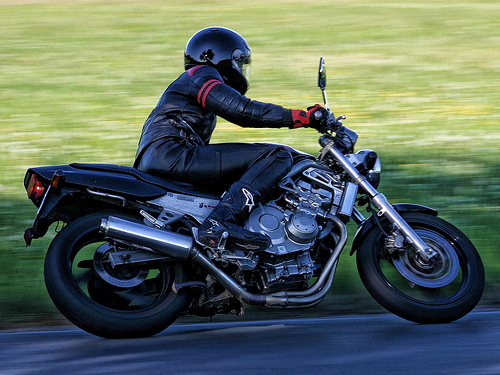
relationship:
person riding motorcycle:
[138, 26, 328, 248] [25, 57, 486, 339]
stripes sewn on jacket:
[193, 78, 222, 108] [133, 65, 293, 167]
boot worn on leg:
[194, 182, 272, 253] [177, 143, 292, 254]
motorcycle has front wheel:
[25, 57, 486, 339] [357, 213, 485, 323]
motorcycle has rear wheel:
[25, 57, 486, 339] [44, 211, 196, 339]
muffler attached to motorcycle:
[98, 215, 194, 257] [25, 57, 486, 339]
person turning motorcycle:
[138, 26, 328, 248] [25, 57, 486, 339]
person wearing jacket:
[138, 26, 328, 248] [133, 65, 293, 167]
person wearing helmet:
[138, 26, 328, 248] [184, 26, 252, 95]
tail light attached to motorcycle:
[26, 173, 46, 198] [25, 57, 486, 339]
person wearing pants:
[138, 26, 328, 248] [134, 137, 317, 194]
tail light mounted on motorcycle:
[26, 173, 46, 198] [25, 57, 486, 339]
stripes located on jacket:
[193, 78, 222, 108] [133, 65, 293, 167]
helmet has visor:
[184, 26, 252, 95] [232, 50, 250, 86]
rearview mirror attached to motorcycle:
[317, 58, 328, 103] [25, 57, 486, 339]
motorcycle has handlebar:
[25, 57, 486, 339] [309, 108, 330, 132]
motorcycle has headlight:
[25, 57, 486, 339] [358, 149, 381, 189]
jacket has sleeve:
[133, 65, 293, 167] [186, 65, 291, 129]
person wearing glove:
[138, 26, 328, 248] [289, 105, 328, 130]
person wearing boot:
[138, 26, 328, 248] [194, 182, 272, 253]